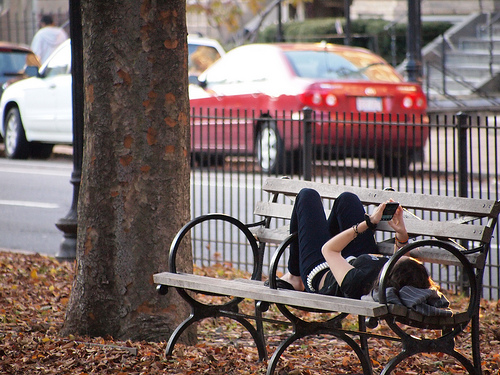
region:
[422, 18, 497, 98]
stairs behind the car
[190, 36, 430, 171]
a red car on the street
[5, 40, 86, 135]
a white car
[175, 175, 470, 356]
a person laying on a bench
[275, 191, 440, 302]
a person holding a phone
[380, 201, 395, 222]
a cell phone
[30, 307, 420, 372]
leaves on the ground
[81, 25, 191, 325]
a trunk of a tree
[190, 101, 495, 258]
a fence behind the bench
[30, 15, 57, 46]
a person walking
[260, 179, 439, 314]
a person on a bench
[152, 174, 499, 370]
a wood and metal bench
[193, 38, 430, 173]
a parked red car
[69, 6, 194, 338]
a gray tree by a road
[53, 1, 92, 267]
a black metal pole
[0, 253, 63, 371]
died leaves on the ground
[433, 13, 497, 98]
a set of gray steps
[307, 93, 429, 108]
red lights on a car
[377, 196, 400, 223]
a black cell phone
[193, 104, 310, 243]
a black iron fence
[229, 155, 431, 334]
the woman is on the bench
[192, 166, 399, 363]
the bench has wood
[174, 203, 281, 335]
a circle is on the bench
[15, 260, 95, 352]
leaves are on the ground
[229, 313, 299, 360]
a black pole under the bench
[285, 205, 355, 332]
the girl is wearing black pants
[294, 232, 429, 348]
the girl is wearing a silver belt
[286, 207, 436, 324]
A person is laying on the bench.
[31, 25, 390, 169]
Cars parked on the side of the road.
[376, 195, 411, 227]
Person is holding the phone.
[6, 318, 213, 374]
Brown leaves on the ground.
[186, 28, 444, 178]
The car is red.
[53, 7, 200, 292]
Tree trunk next to the bench.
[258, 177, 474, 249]
The back part of the bench is wood.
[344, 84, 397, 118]
White license plate on the car.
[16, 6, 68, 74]
A man walking on the sidewalk.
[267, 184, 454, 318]
woman laying on a park bench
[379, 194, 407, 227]
woman holding a cellphone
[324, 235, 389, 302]
woman wearing a black shirt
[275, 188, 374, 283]
woman wearing black jeans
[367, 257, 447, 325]
woman head on a jacket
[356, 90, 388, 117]
license plate on a car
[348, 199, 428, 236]
woman looking at her cellphone